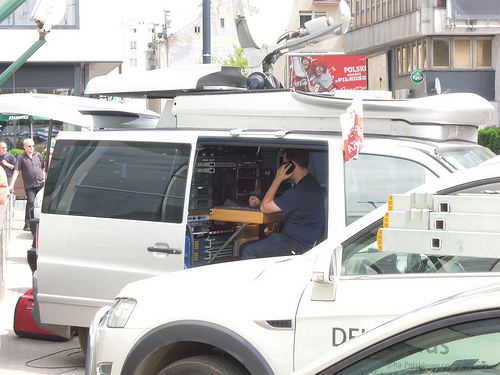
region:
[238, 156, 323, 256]
a man on a phone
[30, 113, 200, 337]
the open door of van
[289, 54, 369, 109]
a coca cola sign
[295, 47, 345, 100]
a clown on a sign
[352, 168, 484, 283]
the end of a ladder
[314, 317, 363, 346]
DE on a vehicle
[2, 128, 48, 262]
a man leaning on something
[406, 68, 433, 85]
a green and white sign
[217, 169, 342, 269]
a man in blue shirt and pants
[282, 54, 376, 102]
a red white and black sign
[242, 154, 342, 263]
the door car is open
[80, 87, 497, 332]
cars are at a stop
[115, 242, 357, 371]
car is white in color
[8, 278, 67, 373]
the bag is on the floor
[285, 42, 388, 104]
poster is beside the road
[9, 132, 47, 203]
man is standing on the road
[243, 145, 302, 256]
the amn is nin the car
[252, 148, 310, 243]
man is dressed in black outfit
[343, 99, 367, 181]
poster is in the car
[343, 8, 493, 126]
buildings ar ajcent to the road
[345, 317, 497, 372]
glass window on vehicle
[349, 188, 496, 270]
glass window on vehicle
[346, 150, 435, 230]
glass window on vehicle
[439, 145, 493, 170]
glass window on vehicle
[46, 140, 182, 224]
glass window on vehicle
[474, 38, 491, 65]
glass window on building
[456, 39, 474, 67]
glass window on building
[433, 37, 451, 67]
glass window on building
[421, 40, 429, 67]
glass window on building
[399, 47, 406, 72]
glass window on building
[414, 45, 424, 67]
glass window on building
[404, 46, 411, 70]
glass window on building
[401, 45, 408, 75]
glass window on building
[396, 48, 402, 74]
glass window on building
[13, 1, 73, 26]
glass window on building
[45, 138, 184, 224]
glass window on vah